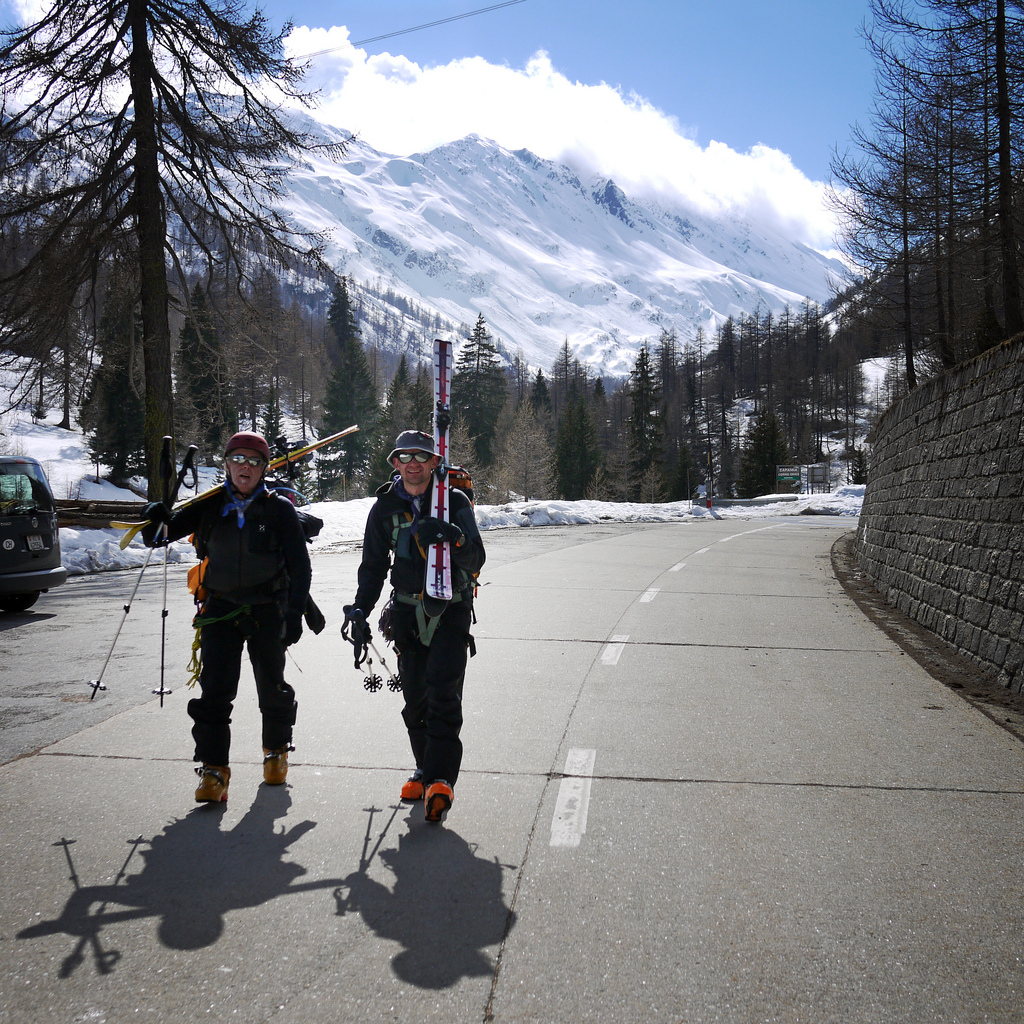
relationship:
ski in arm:
[424, 336, 454, 597] [424, 492, 483, 572]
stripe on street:
[596, 627, 628, 666] [0, 513, 1024, 1017]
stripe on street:
[671, 553, 685, 574] [0, 513, 1024, 1017]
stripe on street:
[716, 520, 797, 543] [0, 513, 1024, 1017]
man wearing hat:
[348, 429, 489, 833] [386, 431, 447, 469]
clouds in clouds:
[0, 0, 1024, 381] [0, 0, 1024, 381]